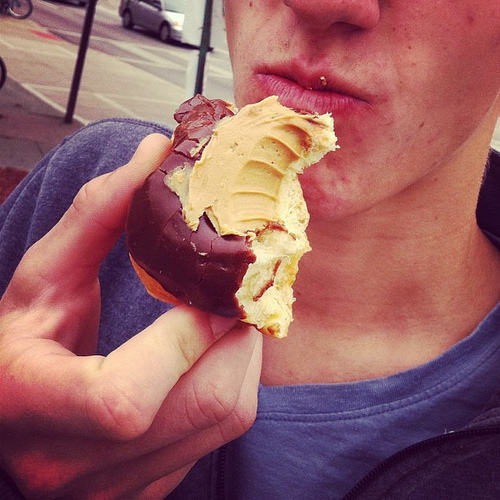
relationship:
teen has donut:
[2, 2, 499, 499] [125, 94, 338, 336]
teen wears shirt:
[2, 2, 499, 499] [4, 115, 499, 495]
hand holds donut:
[1, 133, 260, 497] [125, 94, 338, 336]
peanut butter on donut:
[170, 92, 322, 238] [125, 94, 338, 336]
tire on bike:
[7, 1, 32, 16] [2, 2, 36, 25]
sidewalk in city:
[5, 14, 202, 137] [9, 6, 494, 227]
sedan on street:
[119, 1, 207, 48] [29, 3, 247, 100]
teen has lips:
[2, 2, 499, 499] [252, 60, 369, 121]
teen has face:
[2, 2, 499, 499] [221, 4, 495, 204]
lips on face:
[252, 60, 369, 121] [221, 4, 495, 204]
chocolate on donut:
[124, 95, 246, 316] [125, 94, 338, 336]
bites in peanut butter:
[236, 117, 319, 219] [170, 92, 322, 238]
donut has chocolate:
[125, 94, 338, 336] [124, 95, 246, 316]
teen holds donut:
[2, 2, 499, 499] [125, 94, 338, 336]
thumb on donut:
[37, 133, 166, 268] [125, 94, 338, 336]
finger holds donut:
[25, 302, 233, 441] [125, 94, 338, 336]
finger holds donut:
[51, 329, 251, 475] [125, 94, 338, 336]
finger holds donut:
[114, 341, 264, 484] [125, 94, 338, 336]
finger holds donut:
[152, 464, 201, 497] [125, 94, 338, 336]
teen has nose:
[2, 2, 499, 499] [284, 4, 382, 29]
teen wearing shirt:
[2, 2, 499, 499] [4, 115, 499, 495]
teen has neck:
[2, 2, 499, 499] [249, 130, 484, 282]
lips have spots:
[252, 60, 369, 121] [322, 76, 327, 88]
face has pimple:
[221, 4, 495, 204] [466, 15, 476, 29]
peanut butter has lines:
[170, 92, 322, 238] [248, 156, 284, 175]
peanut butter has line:
[170, 92, 322, 238] [285, 121, 311, 143]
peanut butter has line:
[170, 92, 322, 238] [263, 135, 302, 159]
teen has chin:
[2, 2, 499, 499] [294, 161, 363, 216]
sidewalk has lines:
[5, 14, 202, 137] [24, 81, 129, 143]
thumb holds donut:
[37, 133, 166, 268] [125, 94, 338, 336]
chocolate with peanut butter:
[124, 95, 246, 316] [170, 92, 322, 238]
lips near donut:
[252, 60, 369, 121] [125, 94, 338, 336]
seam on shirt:
[188, 304, 494, 417] [4, 115, 499, 495]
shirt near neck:
[4, 115, 499, 495] [249, 130, 484, 282]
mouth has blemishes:
[252, 60, 369, 121] [247, 95, 369, 154]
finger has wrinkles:
[25, 302, 233, 441] [88, 388, 149, 442]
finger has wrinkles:
[114, 341, 264, 484] [186, 388, 232, 426]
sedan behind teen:
[119, 1, 207, 48] [2, 2, 499, 499]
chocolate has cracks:
[124, 95, 246, 316] [179, 100, 223, 160]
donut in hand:
[125, 94, 338, 336] [1, 133, 260, 497]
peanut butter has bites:
[170, 92, 322, 238] [236, 117, 319, 219]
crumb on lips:
[308, 87, 313, 93] [252, 60, 369, 121]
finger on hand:
[25, 302, 233, 441] [1, 133, 260, 497]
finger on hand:
[152, 464, 201, 497] [1, 133, 260, 497]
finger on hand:
[51, 329, 251, 475] [1, 133, 260, 497]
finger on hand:
[114, 341, 264, 484] [1, 133, 260, 497]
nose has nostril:
[284, 4, 382, 29] [334, 23, 360, 36]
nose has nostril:
[284, 4, 382, 29] [282, 4, 297, 18]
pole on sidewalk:
[191, 1, 218, 96] [5, 14, 202, 137]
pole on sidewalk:
[65, 0, 97, 125] [5, 14, 202, 137]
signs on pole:
[177, 5, 232, 57] [191, 1, 218, 96]